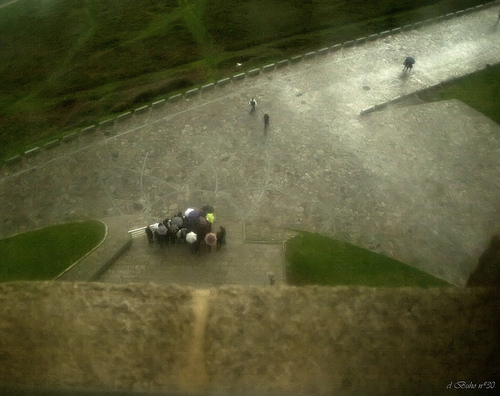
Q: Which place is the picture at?
A: It is at the road.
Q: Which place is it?
A: It is a road.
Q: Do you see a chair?
A: No, there are no chairs.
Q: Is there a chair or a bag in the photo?
A: No, there are no chairs or bags.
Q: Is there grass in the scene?
A: Yes, there is grass.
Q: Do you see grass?
A: Yes, there is grass.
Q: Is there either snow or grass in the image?
A: Yes, there is grass.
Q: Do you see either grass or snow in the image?
A: Yes, there is grass.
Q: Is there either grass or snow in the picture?
A: Yes, there is grass.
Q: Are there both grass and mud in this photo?
A: No, there is grass but no mud.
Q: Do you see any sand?
A: No, there is no sand.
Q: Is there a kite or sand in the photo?
A: No, there are no sand or kites.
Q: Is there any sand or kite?
A: No, there are no sand or kites.